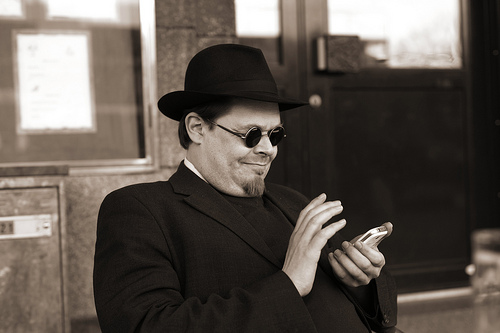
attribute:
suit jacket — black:
[88, 172, 401, 331]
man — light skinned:
[64, 35, 396, 331]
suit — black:
[92, 166, 401, 331]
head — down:
[176, 41, 290, 201]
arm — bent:
[90, 184, 350, 331]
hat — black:
[108, 20, 328, 118]